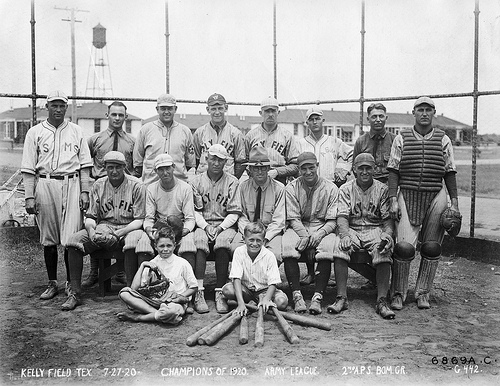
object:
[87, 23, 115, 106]
tower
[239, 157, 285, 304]
man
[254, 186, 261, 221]
tie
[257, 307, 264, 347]
bat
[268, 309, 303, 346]
bat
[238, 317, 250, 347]
bat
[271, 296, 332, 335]
bat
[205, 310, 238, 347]
bat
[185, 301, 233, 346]
bat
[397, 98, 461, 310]
player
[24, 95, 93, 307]
player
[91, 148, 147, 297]
player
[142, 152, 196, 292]
player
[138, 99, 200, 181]
player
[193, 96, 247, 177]
player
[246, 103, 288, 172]
player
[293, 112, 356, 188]
player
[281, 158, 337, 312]
player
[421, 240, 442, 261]
knee-pad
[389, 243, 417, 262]
knee-pad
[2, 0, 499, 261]
fence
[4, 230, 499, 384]
ground